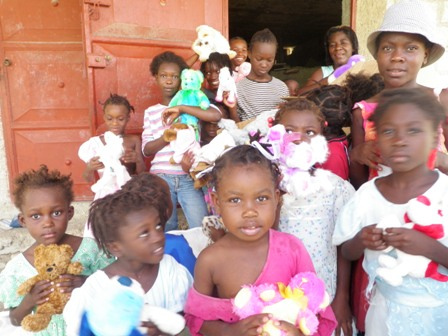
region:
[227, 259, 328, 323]
pink stuffed animal in hand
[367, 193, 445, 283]
red and white stuffed animal in hand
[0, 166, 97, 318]
girl holding brown bear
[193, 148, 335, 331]
girl holding pink stuffed animal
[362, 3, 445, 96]
girl in white hat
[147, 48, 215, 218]
girl holding blue/green bear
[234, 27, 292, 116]
girl in gray shirt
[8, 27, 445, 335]
group of girls holding stuffed animals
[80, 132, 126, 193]
white bear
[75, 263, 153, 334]
blue bear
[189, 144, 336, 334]
a young child posing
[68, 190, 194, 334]
a young child posing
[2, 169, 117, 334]
a young child posing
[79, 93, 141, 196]
a young child posing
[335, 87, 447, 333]
a young child posing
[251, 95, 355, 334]
a young child posing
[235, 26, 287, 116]
a young child posing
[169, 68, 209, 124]
a blue green teddy bear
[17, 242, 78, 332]
a brown teddy bear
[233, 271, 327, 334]
a pink and white teddy bear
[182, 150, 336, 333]
child wearing pink top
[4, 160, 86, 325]
child holding teddy bear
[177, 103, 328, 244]
pink and white in hair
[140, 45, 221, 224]
child holding stuffed bear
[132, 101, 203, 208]
pink and white shirt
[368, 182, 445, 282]
red and white stuffed animal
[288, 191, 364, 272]
white shirt with blue flowers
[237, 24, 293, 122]
person wearing brown striped shirt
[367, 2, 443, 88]
person wearing white hat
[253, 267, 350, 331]
yellow bow on pink and white teddy bear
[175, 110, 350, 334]
a young girl holding a teddy bear.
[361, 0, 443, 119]
a person wearing a hat.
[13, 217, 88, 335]
a brown teddy bear.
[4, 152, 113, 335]
a young girl clutching a teddy bear.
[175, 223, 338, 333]
a pink t shirt on a young girl.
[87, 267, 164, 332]
a blue and white teddy bear.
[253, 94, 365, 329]
a little girl holding a mostly white teddy bear.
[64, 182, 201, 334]
a young girl holding a blue stuffed boy.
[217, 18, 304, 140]
a young child with short hair.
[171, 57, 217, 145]
a blue teddy bear.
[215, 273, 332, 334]
a pink and white bear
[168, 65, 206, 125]
a large green bear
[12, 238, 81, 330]
part of a brown bear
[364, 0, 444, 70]
a woman's gray hat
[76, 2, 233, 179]
part of a large red door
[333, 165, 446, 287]
part of a girl's white shirt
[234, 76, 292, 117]
a boy's striped shirt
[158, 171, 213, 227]
a girl's blue jean pants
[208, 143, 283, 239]
the head of a girl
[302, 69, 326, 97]
the arm of a woman